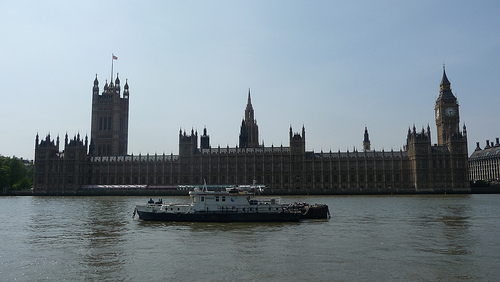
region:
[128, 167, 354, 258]
this is a boat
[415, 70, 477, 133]
this is a clock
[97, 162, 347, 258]
the boat is in water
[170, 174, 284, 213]
the boat is white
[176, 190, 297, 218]
multiple windows on boat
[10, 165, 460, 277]
the water is green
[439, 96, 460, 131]
face of clock is white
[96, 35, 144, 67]
flag on top of building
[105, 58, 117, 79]
flag pole on top of building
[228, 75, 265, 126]
steeple on top of building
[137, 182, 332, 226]
a boat is on the water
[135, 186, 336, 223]
a boat is on the river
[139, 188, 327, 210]
the boat is painted white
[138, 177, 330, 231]
the boat is in profile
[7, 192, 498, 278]
the river is calm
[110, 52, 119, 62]
a flag is on the tower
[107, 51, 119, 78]
a mast is on the tower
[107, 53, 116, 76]
the flag is on a mast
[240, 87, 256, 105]
the building has a spire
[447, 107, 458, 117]
a clock is on the tower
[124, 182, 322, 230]
boat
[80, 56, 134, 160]
tower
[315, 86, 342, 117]
white clouds in blue sky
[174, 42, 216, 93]
white clouds in blue sky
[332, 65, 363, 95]
white clouds in blue sky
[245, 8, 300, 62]
white clouds in blue sky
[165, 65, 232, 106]
white clouds in blue sky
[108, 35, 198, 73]
white clouds in blue sky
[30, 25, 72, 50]
white clouds in blue sky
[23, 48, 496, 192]
a big building in road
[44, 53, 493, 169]
a big building in ground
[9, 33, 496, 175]
a big building in earth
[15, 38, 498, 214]
a big building near water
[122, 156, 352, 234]
a boat in water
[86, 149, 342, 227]
a boat travelling in water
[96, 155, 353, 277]
a boat floating in water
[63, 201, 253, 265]
a clean undisturbed water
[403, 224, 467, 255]
riddles in the water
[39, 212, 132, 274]
the water is a brownish color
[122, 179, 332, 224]
the boat is big and long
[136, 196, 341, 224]
the boat is white and brown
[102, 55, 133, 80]
the flag is hanging on top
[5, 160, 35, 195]
the green tree is beside building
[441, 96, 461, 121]
the clock is on the bulding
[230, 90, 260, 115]
the building has a sharp point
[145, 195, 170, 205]
people was on the big boat